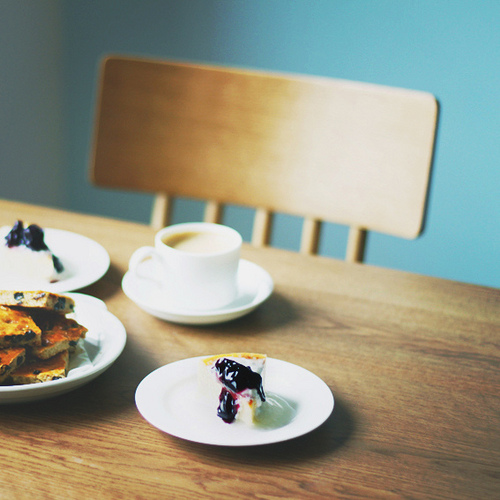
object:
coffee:
[168, 231, 233, 254]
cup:
[129, 235, 246, 312]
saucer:
[120, 259, 275, 320]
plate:
[135, 350, 337, 445]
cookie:
[0, 288, 87, 376]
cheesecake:
[207, 355, 269, 421]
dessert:
[0, 219, 68, 284]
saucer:
[43, 224, 110, 292]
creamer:
[192, 233, 213, 249]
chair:
[87, 57, 445, 224]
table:
[0, 242, 498, 499]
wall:
[0, 0, 499, 250]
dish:
[135, 352, 336, 443]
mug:
[130, 222, 244, 306]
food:
[211, 350, 270, 428]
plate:
[0, 227, 107, 293]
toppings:
[209, 362, 258, 388]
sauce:
[30, 224, 44, 248]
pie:
[0, 216, 67, 286]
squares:
[9, 294, 82, 382]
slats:
[153, 203, 376, 249]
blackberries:
[4, 216, 49, 254]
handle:
[127, 243, 159, 288]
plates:
[0, 223, 337, 452]